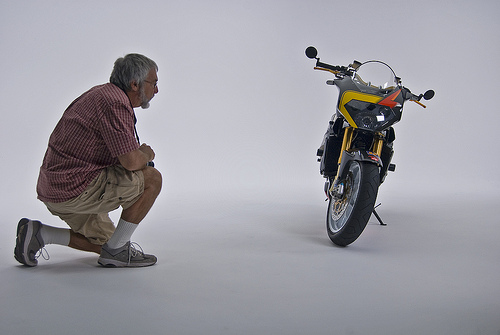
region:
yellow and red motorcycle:
[303, 43, 433, 250]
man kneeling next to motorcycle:
[12, 48, 170, 275]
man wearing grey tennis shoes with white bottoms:
[8, 215, 160, 272]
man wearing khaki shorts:
[44, 163, 148, 248]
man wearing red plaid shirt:
[37, 83, 143, 203]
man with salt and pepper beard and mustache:
[110, 53, 159, 112]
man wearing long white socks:
[40, 214, 140, 266]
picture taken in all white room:
[5, 8, 498, 324]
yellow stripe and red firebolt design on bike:
[335, 85, 405, 162]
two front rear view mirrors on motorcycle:
[305, 44, 442, 100]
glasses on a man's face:
[141, 76, 158, 90]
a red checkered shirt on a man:
[34, 85, 137, 204]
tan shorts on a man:
[41, 168, 142, 247]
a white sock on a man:
[107, 218, 140, 248]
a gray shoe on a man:
[97, 241, 158, 266]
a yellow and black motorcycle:
[301, 44, 435, 246]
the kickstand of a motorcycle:
[371, 204, 389, 230]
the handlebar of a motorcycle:
[313, 58, 350, 78]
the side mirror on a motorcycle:
[301, 44, 321, 60]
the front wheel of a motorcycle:
[321, 150, 383, 248]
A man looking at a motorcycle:
[7, 40, 437, 273]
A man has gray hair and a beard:
[105, 50, 162, 112]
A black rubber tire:
[317, 152, 379, 249]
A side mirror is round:
[296, 36, 318, 61]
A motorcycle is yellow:
[295, 35, 436, 251]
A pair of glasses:
[137, 72, 161, 94]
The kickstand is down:
[365, 196, 390, 231]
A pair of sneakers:
[10, 210, 162, 271]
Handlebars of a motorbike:
[300, 40, 438, 115]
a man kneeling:
[14, 48, 298, 289]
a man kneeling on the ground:
[12, 39, 214, 301]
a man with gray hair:
[83, 36, 210, 291]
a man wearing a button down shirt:
[65, 51, 187, 233]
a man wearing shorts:
[58, 55, 203, 237]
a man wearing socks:
[39, 47, 217, 324]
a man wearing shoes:
[1, 43, 222, 296]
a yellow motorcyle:
[273, 16, 485, 304]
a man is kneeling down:
[54, 71, 224, 278]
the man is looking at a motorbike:
[38, 47, 238, 319]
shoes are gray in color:
[94, 240, 166, 274]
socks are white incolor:
[107, 202, 146, 262]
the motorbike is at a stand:
[323, 33, 413, 268]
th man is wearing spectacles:
[95, 57, 180, 238]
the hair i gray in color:
[93, 30, 160, 80]